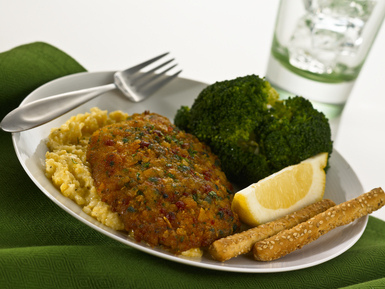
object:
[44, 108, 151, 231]
egg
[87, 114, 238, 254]
cutlet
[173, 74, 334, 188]
broccoli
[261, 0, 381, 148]
glass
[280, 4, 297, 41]
water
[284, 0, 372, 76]
ice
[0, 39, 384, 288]
table cloth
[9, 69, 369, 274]
plate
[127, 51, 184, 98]
prongs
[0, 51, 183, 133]
fork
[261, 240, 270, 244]
seeds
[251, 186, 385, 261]
breadstick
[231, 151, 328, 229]
lemon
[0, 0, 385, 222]
background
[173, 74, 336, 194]
something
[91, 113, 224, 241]
vegetable